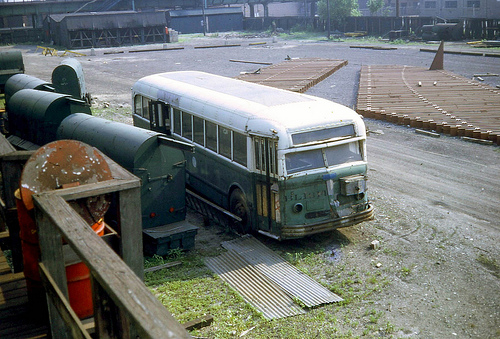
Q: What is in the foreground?
A: A bus.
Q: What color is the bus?
A: Green and white.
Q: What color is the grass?
A: Green.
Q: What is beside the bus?
A: A parking lot.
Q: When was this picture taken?
A: Daytime.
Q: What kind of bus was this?
A: A VW.